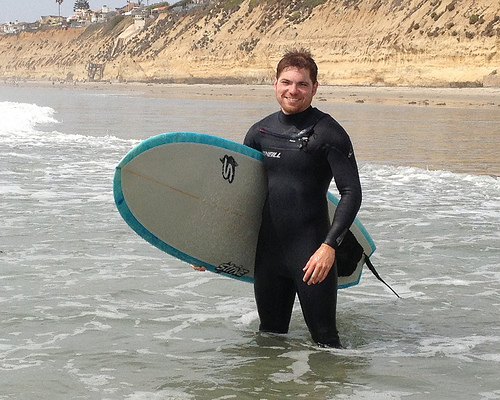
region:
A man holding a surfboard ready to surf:
[109, 46, 410, 361]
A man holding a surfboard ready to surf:
[100, 43, 407, 354]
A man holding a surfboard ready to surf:
[110, 47, 402, 348]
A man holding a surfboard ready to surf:
[105, 45, 410, 343]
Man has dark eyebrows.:
[277, 78, 327, 87]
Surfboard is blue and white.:
[145, 120, 273, 260]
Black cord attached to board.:
[352, 240, 407, 298]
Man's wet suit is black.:
[244, 110, 341, 328]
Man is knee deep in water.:
[226, 295, 367, 370]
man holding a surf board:
[121, 94, 383, 301]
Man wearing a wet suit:
[211, 95, 360, 355]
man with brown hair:
[263, 42, 326, 92]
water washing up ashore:
[49, 74, 270, 156]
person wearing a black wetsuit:
[235, 119, 365, 316]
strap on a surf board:
[351, 238, 414, 303]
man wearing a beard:
[266, 88, 313, 115]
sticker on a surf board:
[211, 142, 241, 192]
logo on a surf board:
[203, 250, 255, 286]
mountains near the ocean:
[40, 15, 290, 57]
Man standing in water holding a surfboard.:
[0, 48, 498, 398]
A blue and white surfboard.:
[111, 130, 375, 289]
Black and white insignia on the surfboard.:
[217, 153, 237, 181]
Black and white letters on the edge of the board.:
[212, 260, 248, 276]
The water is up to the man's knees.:
[2, 332, 497, 397]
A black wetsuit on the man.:
[243, 106, 361, 348]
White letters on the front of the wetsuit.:
[260, 145, 282, 161]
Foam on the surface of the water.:
[0, 100, 497, 399]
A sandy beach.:
[0, 80, 497, 175]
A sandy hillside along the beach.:
[0, 0, 498, 86]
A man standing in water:
[240, 51, 365, 348]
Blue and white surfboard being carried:
[110, 125, 380, 289]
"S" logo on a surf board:
[216, 153, 240, 184]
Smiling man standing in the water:
[113, 50, 376, 348]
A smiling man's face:
[272, 50, 321, 115]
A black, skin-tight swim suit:
[243, 105, 362, 349]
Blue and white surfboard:
[114, 130, 376, 288]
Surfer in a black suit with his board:
[111, 50, 377, 346]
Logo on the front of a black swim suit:
[260, 146, 284, 162]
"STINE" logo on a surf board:
[213, 260, 248, 278]